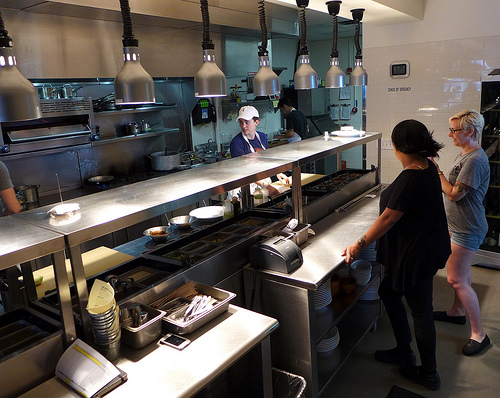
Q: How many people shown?
A: 5.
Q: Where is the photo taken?
A: Kitchen.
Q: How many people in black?
A: 2.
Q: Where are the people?
A: A kitchen.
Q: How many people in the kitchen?
A: Four.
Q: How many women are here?
A: Two.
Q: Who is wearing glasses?
A: The blonde woman.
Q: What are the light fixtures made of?
A: Metal.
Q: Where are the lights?
A: Hanging from the ceiling.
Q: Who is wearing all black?
A: The brunette lady.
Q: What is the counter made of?
A: Metal.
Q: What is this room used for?
A: Cooking.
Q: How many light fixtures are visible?
A: Seven.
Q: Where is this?
A: Restaurant kitchen.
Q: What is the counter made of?
A: Stainless steel.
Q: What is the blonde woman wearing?
A: Shorts and a t-shirt.